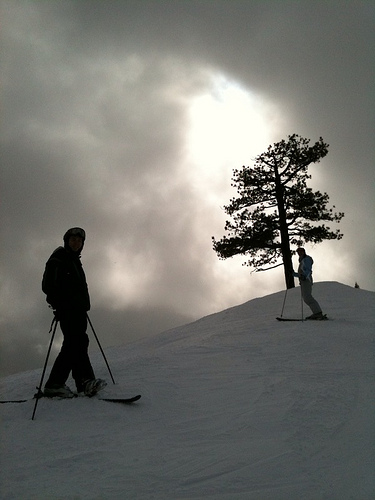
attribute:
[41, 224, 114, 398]
skier — smiling, sking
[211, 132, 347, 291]
tree — single, green, evergreen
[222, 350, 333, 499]
snow — white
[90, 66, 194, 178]
clouds — grey, white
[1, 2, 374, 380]
sky — grey, cloudy, dark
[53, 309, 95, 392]
pants — black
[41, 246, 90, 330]
jacket — blue, black